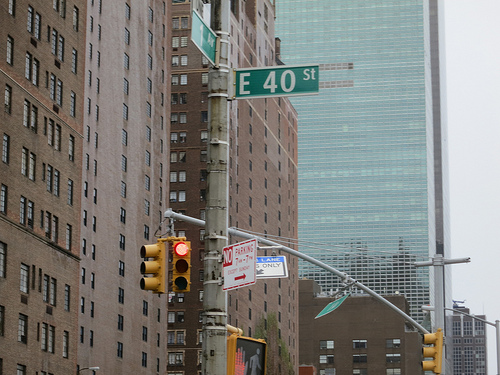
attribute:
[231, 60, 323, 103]
sign — green, rectangular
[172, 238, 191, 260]
light — red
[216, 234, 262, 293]
sign — white, red, no parking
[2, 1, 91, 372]
building — brick, brown, tall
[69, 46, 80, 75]
window — small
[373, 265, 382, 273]
window — glass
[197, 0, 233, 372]
pole — grey, metal, silver, tall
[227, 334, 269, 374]
sign — pedestrian, walking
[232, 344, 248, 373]
hand — red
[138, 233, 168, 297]
lantern — yellow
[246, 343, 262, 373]
person — white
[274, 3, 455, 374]
building — tall, glass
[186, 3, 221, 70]
sign — second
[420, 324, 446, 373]
light — second